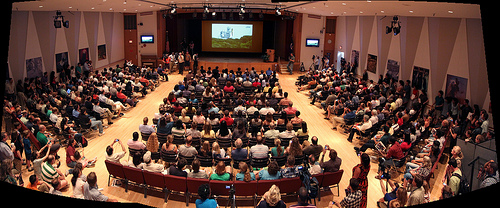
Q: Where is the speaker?
A: By the podium.